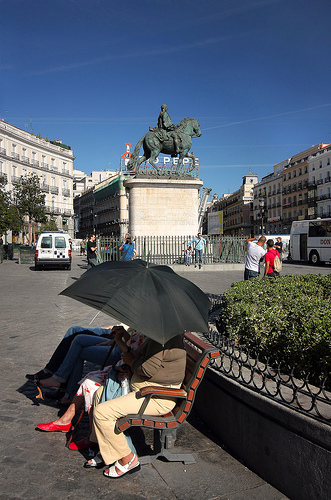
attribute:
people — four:
[19, 306, 193, 480]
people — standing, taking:
[241, 235, 279, 279]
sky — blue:
[116, 12, 282, 119]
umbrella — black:
[44, 234, 227, 349]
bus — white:
[289, 216, 330, 264]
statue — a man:
[126, 102, 201, 181]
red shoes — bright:
[33, 419, 88, 450]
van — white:
[35, 221, 74, 266]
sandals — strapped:
[97, 450, 142, 478]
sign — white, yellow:
[206, 208, 223, 238]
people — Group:
[26, 321, 184, 476]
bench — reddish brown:
[40, 271, 254, 486]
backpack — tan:
[274, 254, 281, 272]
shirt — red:
[264, 246, 280, 273]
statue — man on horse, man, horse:
[125, 95, 208, 181]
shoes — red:
[35, 416, 89, 450]